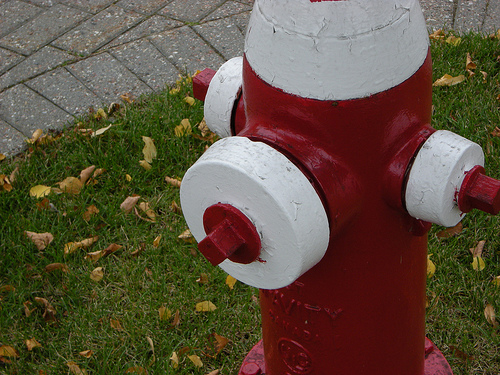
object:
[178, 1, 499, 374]
fire hydrant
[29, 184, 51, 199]
leaf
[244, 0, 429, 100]
top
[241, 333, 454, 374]
base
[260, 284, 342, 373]
sign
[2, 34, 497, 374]
grass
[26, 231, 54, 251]
leaf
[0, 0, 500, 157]
sidewalk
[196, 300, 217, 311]
leaf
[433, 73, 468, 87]
leaf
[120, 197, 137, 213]
leaf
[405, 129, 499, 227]
side part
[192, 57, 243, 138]
side part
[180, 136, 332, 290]
side part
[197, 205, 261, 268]
bolt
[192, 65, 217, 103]
bolt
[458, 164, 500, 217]
bolt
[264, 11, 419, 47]
cracked paint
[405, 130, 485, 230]
base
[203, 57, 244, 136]
base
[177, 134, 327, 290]
base